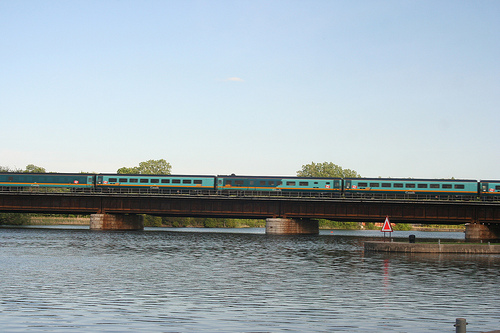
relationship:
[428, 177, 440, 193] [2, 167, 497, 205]
window on passenger train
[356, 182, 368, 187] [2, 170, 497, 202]
window on train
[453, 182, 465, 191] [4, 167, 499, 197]
window on train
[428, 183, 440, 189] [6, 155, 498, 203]
window on train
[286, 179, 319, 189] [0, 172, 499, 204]
window on train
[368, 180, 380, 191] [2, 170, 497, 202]
window on train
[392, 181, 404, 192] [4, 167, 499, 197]
window on train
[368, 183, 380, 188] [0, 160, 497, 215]
window on train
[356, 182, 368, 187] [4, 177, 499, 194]
window on train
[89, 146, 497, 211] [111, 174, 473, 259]
train on bridge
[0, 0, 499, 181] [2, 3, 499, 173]
clouds in sky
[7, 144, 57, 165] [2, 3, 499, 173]
clouds in sky